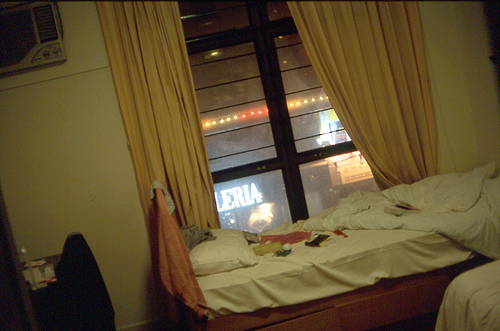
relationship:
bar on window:
[187, 37, 346, 159] [125, 1, 444, 241]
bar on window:
[187, 37, 346, 159] [156, 2, 375, 198]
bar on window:
[276, 40, 303, 50] [273, 30, 350, 153]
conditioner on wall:
[1, 7, 70, 77] [3, 0, 497, 298]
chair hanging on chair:
[53, 231, 116, 329] [27, 220, 111, 329]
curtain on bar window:
[93, 1, 220, 229] [180, 7, 371, 219]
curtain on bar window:
[281, 6, 449, 191] [180, 7, 371, 219]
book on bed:
[305, 233, 335, 247] [151, 177, 497, 329]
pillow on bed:
[186, 227, 258, 275] [147, 156, 494, 324]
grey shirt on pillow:
[180, 224, 218, 251] [192, 224, 257, 274]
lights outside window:
[213, 95, 315, 124] [177, 6, 386, 221]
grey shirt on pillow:
[182, 224, 218, 247] [188, 225, 258, 273]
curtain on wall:
[93, 1, 219, 229] [3, 0, 497, 298]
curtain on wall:
[287, 0, 439, 190] [3, 0, 497, 298]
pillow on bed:
[186, 228, 258, 275] [206, 204, 477, 321]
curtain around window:
[93, 1, 220, 229] [175, 3, 399, 236]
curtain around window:
[287, 0, 439, 190] [175, 3, 399, 236]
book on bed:
[305, 231, 332, 251] [147, 156, 494, 324]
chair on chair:
[53, 231, 116, 329] [32, 236, 128, 329]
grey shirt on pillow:
[180, 224, 218, 251] [186, 227, 258, 275]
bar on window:
[187, 37, 346, 159] [175, 3, 399, 236]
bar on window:
[187, 37, 346, 159] [173, 6, 373, 227]